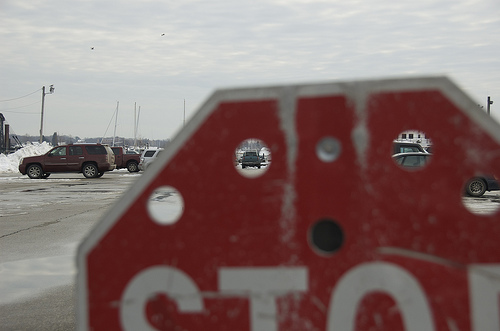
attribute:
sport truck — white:
[18, 127, 133, 239]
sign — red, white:
[58, 84, 490, 329]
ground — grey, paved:
[1, 168, 498, 329]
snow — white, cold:
[1, 141, 56, 177]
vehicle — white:
[14, 108, 129, 192]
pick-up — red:
[101, 143, 145, 173]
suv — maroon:
[16, 141, 119, 180]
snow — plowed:
[3, 126, 61, 178]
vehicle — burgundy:
[8, 134, 120, 188]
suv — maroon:
[20, 138, 112, 183]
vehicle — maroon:
[17, 130, 117, 185]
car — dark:
[34, 133, 104, 191]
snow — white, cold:
[0, 140, 44, 156]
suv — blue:
[243, 150, 260, 170]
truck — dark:
[15, 102, 168, 215]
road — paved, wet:
[6, 156, 166, 329]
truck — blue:
[237, 148, 264, 172]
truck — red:
[109, 143, 141, 170]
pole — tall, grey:
[5, 75, 65, 172]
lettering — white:
[115, 262, 497, 327]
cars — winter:
[14, 142, 158, 186]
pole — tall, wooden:
[16, 86, 66, 153]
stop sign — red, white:
[71, 70, 497, 328]